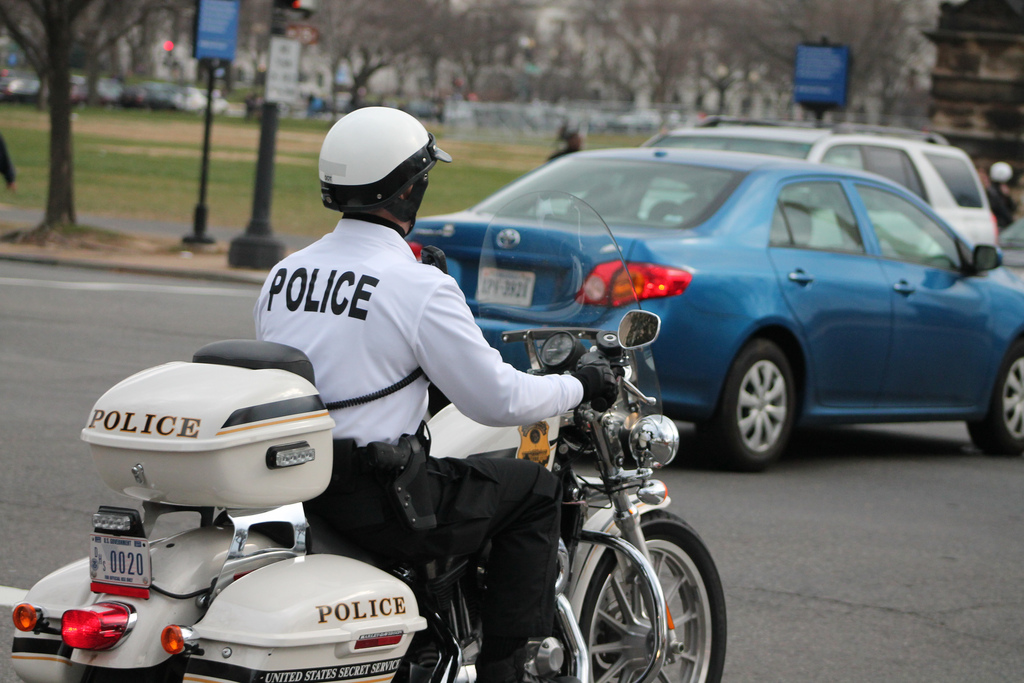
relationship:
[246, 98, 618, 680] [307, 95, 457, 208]
police officer wearing helmet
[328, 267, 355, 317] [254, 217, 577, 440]
letter on shirt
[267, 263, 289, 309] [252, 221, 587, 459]
letter on shirt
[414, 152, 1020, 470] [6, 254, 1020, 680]
car driving on road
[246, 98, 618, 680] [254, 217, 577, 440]
police officer wearing shirt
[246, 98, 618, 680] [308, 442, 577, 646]
police officer wearing pants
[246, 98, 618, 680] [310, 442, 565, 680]
police officer wearing pants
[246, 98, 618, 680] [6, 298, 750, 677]
police officer on motorcycle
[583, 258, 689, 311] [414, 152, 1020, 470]
light on back of car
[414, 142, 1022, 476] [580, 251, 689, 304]
car with tailight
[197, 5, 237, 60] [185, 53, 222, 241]
sign on pole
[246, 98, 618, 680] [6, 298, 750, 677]
police officer rides motorcycle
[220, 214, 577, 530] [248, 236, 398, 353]
shirt with word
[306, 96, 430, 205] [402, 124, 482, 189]
helmet with a visor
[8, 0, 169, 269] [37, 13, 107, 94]
tree with branches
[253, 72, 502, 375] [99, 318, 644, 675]
cop on a motorcycle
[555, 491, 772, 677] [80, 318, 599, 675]
tire on a motorcycle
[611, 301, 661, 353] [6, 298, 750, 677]
mirror on a motorcycle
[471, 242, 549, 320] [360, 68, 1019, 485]
license plate on a car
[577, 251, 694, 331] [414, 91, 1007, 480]
tail light on a car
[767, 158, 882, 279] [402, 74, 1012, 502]
window on a car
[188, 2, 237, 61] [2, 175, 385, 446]
sign near street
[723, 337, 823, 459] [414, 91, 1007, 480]
tire of a car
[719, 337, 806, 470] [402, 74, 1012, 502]
tire of a car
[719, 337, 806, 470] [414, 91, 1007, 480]
tire of a car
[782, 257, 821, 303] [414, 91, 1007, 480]
handle of a car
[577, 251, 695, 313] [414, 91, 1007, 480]
tail light of a car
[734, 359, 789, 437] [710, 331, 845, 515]
rim of a tire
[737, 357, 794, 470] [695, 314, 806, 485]
rim of a tire